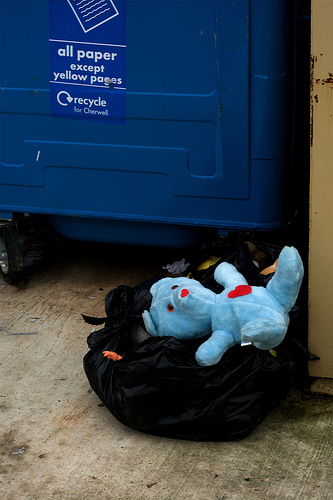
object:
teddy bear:
[138, 245, 305, 368]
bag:
[80, 239, 315, 441]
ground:
[0, 234, 332, 499]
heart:
[226, 282, 252, 299]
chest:
[211, 289, 236, 329]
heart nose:
[180, 288, 188, 299]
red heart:
[227, 280, 253, 302]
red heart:
[181, 288, 192, 300]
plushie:
[218, 298, 238, 330]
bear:
[141, 244, 303, 369]